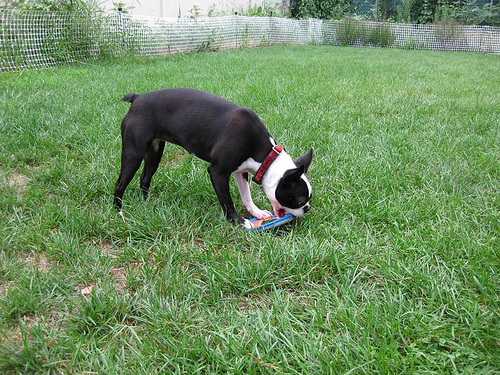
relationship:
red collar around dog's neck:
[248, 137, 279, 183] [240, 126, 296, 193]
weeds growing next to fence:
[333, 15, 396, 47] [345, 10, 468, 56]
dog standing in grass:
[110, 86, 312, 231] [0, 38, 494, 371]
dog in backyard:
[110, 86, 312, 231] [0, 42, 499, 374]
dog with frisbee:
[110, 86, 312, 231] [246, 211, 292, 231]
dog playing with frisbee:
[110, 86, 312, 231] [240, 200, 309, 238]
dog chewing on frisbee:
[110, 86, 312, 231] [236, 204, 305, 239]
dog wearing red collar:
[110, 86, 312, 231] [248, 143, 283, 185]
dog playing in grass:
[110, 86, 312, 231] [58, 43, 473, 343]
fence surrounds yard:
[1, 15, 500, 77] [14, 70, 480, 360]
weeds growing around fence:
[331, 22, 409, 47] [1, 15, 500, 77]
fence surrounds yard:
[1, 19, 481, 77] [14, 70, 480, 360]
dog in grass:
[110, 86, 312, 231] [0, 38, 494, 371]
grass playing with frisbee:
[0, 38, 494, 371] [254, 204, 302, 234]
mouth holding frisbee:
[273, 202, 302, 222] [242, 212, 295, 233]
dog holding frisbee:
[110, 86, 312, 231] [242, 212, 295, 233]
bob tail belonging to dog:
[119, 90, 139, 102] [110, 86, 312, 231]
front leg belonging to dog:
[232, 169, 272, 220] [110, 86, 312, 231]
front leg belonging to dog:
[206, 162, 254, 229] [110, 86, 312, 231]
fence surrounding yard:
[1, 15, 500, 77] [1, 43, 484, 373]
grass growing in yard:
[0, 38, 494, 371] [1, 43, 484, 373]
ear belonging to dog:
[282, 161, 307, 190] [110, 86, 312, 231]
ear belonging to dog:
[292, 144, 314, 173] [110, 86, 312, 231]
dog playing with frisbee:
[110, 86, 312, 231] [241, 210, 296, 233]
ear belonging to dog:
[282, 164, 305, 186] [110, 86, 312, 231]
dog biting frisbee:
[112, 86, 313, 219] [253, 215, 299, 227]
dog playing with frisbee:
[112, 86, 313, 219] [248, 212, 295, 229]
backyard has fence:
[8, 66, 490, 358] [6, 6, 494, 55]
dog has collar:
[112, 86, 313, 219] [249, 144, 287, 180]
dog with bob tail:
[110, 86, 312, 231] [119, 90, 139, 102]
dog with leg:
[112, 86, 313, 219] [108, 121, 135, 209]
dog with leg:
[112, 86, 313, 219] [140, 138, 165, 191]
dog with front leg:
[112, 86, 313, 219] [206, 167, 238, 220]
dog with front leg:
[112, 86, 313, 219] [232, 169, 257, 212]